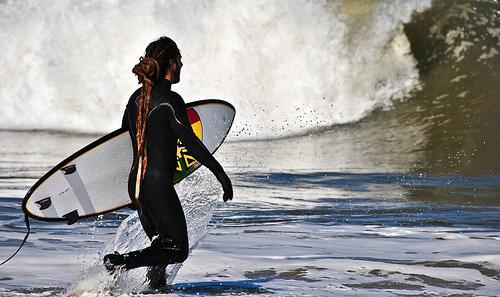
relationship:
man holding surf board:
[104, 37, 232, 291] [10, 95, 250, 206]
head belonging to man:
[131, 37, 177, 85] [104, 37, 232, 291]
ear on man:
[164, 56, 176, 71] [104, 37, 232, 291]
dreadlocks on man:
[126, 39, 163, 181] [104, 37, 232, 291]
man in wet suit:
[92, 19, 225, 253] [112, 80, 231, 294]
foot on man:
[94, 253, 134, 283] [112, 23, 242, 293]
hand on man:
[216, 170, 233, 203] [104, 37, 232, 291]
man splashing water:
[104, 37, 232, 291] [0, 1, 497, 293]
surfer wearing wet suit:
[102, 36, 232, 293] [120, 85, 236, 294]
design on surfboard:
[172, 104, 203, 174] [20, 99, 237, 218]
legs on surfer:
[102, 167, 191, 292] [102, 36, 232, 293]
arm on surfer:
[172, 87, 236, 199] [102, 36, 232, 293]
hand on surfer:
[216, 170, 233, 203] [102, 36, 232, 293]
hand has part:
[216, 170, 233, 203] [222, 185, 231, 190]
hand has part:
[208, 164, 244, 206] [224, 178, 227, 185]